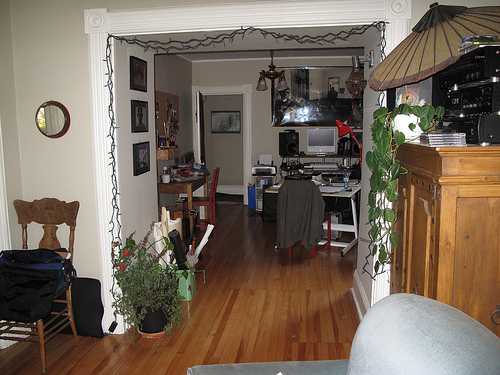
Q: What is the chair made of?
A: Wood.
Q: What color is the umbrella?
A: Tan and brown.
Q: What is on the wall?
A: String of lights.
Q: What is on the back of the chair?
A: Jacket.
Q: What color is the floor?
A: Brown.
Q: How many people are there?
A: None.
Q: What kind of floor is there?
A: Hardwood.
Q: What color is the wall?
A: White.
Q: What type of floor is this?
A: Hardwood.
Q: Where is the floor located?
A: Office.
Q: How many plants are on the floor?
A: One.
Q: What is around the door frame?
A: Lights.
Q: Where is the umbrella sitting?
A: Corner.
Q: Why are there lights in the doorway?
A: Decoration.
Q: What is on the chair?
A: Suitcase.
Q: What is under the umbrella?
A: Stereo.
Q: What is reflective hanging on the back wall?
A: A mirror.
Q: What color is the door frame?
A: White.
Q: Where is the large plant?
A: On the floor.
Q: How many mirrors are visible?
A: One.